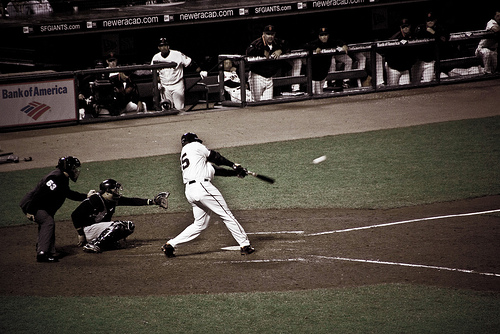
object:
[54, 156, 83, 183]
helmet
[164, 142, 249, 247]
uniform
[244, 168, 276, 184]
bat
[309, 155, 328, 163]
ball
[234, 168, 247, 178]
glove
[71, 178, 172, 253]
man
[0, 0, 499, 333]
game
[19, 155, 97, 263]
umpire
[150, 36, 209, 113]
players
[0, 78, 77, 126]
advert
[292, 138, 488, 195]
grass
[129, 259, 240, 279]
dirt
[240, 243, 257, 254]
plate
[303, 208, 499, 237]
line